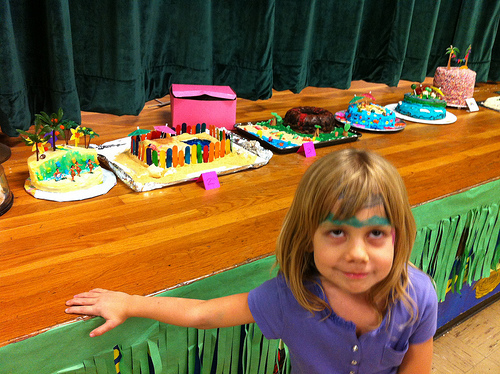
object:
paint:
[322, 211, 391, 231]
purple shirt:
[248, 263, 439, 374]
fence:
[132, 121, 232, 166]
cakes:
[434, 45, 477, 105]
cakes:
[396, 82, 447, 119]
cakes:
[336, 90, 410, 130]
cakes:
[235, 104, 363, 152]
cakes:
[90, 123, 272, 193]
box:
[171, 83, 239, 134]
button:
[351, 358, 358, 366]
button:
[353, 346, 359, 352]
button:
[348, 370, 357, 372]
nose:
[344, 237, 372, 264]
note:
[197, 171, 219, 190]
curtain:
[0, 0, 497, 137]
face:
[314, 202, 397, 292]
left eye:
[366, 228, 388, 243]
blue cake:
[394, 83, 446, 120]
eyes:
[327, 227, 350, 237]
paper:
[18, 185, 500, 371]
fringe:
[8, 170, 498, 371]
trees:
[34, 105, 79, 151]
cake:
[28, 141, 107, 200]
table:
[1, 57, 499, 371]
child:
[66, 146, 437, 373]